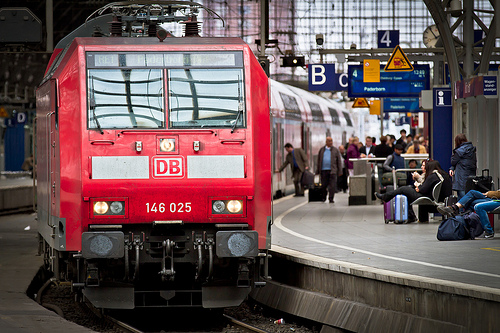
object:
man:
[276, 142, 311, 197]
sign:
[426, 73, 458, 113]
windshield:
[87, 50, 248, 128]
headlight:
[212, 198, 244, 213]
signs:
[382, 47, 410, 70]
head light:
[92, 201, 124, 215]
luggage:
[301, 162, 498, 243]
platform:
[266, 153, 497, 330]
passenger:
[317, 135, 343, 202]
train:
[38, 31, 410, 328]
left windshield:
[81, 66, 167, 133]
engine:
[31, 0, 271, 309]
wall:
[0, 0, 32, 175]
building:
[3, 2, 498, 204]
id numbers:
[146, 199, 193, 215]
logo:
[151, 155, 183, 176]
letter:
[429, 87, 449, 107]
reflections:
[79, 60, 246, 127]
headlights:
[207, 193, 247, 213]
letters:
[309, 63, 419, 99]